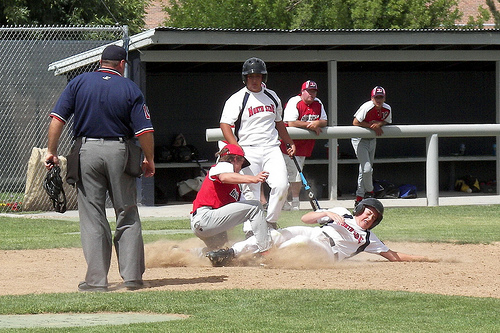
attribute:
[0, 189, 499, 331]
ground — sandy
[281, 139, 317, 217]
baseball bat — white , blue , Black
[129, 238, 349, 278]
dust — swirling in the air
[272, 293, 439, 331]
grass — green 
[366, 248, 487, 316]
sand — brown 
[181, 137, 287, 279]
player — red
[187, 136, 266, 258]
uniform — white 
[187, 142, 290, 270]
catcher — red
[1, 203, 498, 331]
grass — green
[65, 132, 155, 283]
pants — grey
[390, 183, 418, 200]
bag — blue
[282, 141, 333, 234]
bat — black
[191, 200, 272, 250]
pants — grey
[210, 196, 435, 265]
player — baseball player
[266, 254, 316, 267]
base — home base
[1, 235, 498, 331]
dirt — light brown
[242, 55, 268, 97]
helmet — Black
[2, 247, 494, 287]
dirt — brown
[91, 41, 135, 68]
cap — blue